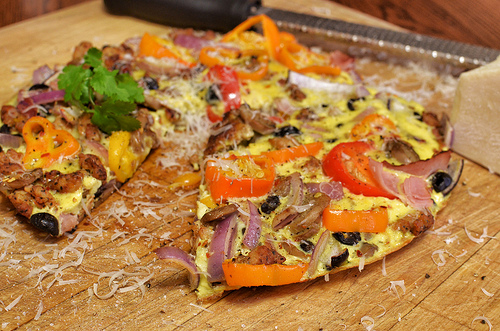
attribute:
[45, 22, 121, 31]
table — wood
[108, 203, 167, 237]
cheese — grated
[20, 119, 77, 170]
pepper — orange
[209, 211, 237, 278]
onion — red, purple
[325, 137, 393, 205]
tomato — red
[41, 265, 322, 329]
board — wood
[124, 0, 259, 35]
handle — black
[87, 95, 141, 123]
lettuce — green